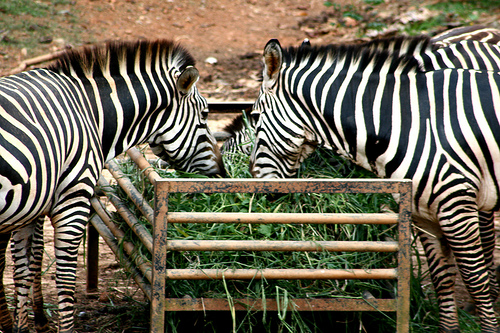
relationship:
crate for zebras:
[85, 101, 412, 333] [2, 26, 499, 332]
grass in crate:
[103, 112, 430, 332] [85, 97, 412, 331]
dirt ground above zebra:
[86, 3, 381, 101] [248, 35, 498, 331]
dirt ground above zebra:
[86, 3, 381, 101] [0, 37, 229, 327]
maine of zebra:
[55, 39, 196, 75] [0, 37, 229, 327]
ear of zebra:
[177, 67, 200, 94] [0, 37, 229, 327]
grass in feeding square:
[136, 154, 390, 298] [84, 99, 413, 330]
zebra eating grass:
[248, 35, 498, 331] [139, 154, 396, 298]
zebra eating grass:
[0, 37, 229, 327] [139, 154, 396, 298]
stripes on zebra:
[299, 61, 499, 166] [214, 47, 499, 214]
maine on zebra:
[68, 34, 258, 75] [24, 39, 245, 216]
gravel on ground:
[146, 7, 324, 59] [164, 21, 315, 53]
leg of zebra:
[48, 152, 97, 332] [0, 37, 229, 327]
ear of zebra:
[173, 62, 203, 101] [0, 21, 498, 331]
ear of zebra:
[258, 32, 289, 90] [0, 21, 498, 331]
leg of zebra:
[439, 200, 498, 330] [235, 27, 498, 279]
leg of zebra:
[9, 228, 47, 331] [0, 37, 229, 327]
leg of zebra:
[9, 219, 43, 331] [13, 44, 219, 169]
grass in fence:
[136, 154, 390, 298] [82, 144, 414, 328]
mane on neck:
[278, 40, 427, 78] [273, 40, 426, 177]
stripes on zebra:
[299, 61, 499, 166] [248, 35, 498, 331]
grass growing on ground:
[136, 154, 390, 298] [156, 7, 337, 92]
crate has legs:
[85, 101, 412, 333] [82, 209, 104, 292]